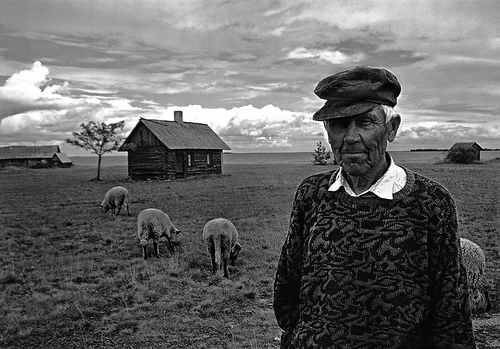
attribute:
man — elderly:
[303, 73, 461, 329]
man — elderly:
[274, 51, 461, 343]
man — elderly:
[253, 61, 478, 346]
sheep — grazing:
[458, 238, 493, 320]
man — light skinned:
[266, 45, 481, 307]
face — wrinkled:
[318, 103, 401, 187]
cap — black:
[308, 64, 405, 124]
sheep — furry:
[195, 202, 260, 292]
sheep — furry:
[455, 232, 488, 309]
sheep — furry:
[97, 177, 132, 212]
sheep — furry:
[134, 202, 184, 260]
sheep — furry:
[201, 212, 246, 274]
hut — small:
[442, 137, 491, 172]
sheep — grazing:
[196, 210, 251, 285]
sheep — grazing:
[128, 197, 183, 265]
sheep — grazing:
[91, 181, 133, 222]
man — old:
[272, 67, 476, 347]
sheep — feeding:
[198, 217, 250, 284]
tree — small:
[66, 116, 128, 184]